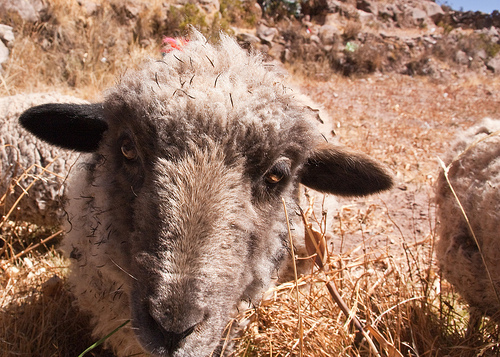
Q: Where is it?
A: This is at the field.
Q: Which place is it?
A: It is a field.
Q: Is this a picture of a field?
A: Yes, it is showing a field.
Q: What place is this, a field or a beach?
A: It is a field.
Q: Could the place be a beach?
A: No, it is a field.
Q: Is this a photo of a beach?
A: No, the picture is showing a field.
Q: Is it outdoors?
A: Yes, it is outdoors.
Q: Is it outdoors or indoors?
A: It is outdoors.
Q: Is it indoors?
A: No, it is outdoors.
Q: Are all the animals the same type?
A: Yes, all the animals are sheep.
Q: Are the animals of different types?
A: No, all the animals are sheep.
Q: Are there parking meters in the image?
A: No, there are no parking meters.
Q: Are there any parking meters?
A: No, there are no parking meters.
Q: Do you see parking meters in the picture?
A: No, there are no parking meters.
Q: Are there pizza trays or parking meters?
A: No, there are no parking meters or pizza trays.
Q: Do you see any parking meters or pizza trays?
A: No, there are no parking meters or pizza trays.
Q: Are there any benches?
A: No, there are no benches.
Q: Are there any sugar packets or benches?
A: No, there are no benches or sugar packets.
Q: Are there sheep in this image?
A: Yes, there is a sheep.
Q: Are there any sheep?
A: Yes, there is a sheep.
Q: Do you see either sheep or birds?
A: Yes, there is a sheep.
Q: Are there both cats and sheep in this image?
A: No, there is a sheep but no cats.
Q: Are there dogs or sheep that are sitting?
A: Yes, the sheep is sitting.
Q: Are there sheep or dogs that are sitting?
A: Yes, the sheep is sitting.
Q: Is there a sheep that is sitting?
A: Yes, there is a sheep that is sitting.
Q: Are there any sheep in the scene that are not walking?
A: Yes, there is a sheep that is sitting.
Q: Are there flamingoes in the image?
A: No, there are no flamingoes.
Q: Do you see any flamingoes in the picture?
A: No, there are no flamingoes.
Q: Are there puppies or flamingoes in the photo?
A: No, there are no flamingoes or puppies.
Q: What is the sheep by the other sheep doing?
A: The sheep is sitting.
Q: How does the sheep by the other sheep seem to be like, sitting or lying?
A: The sheep is sitting.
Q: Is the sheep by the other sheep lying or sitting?
A: The sheep is sitting.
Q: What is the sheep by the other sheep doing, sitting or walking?
A: The sheep is sitting.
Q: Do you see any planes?
A: No, there are no planes.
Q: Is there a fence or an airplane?
A: No, there are no airplanes or fences.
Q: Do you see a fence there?
A: No, there are no fences.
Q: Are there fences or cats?
A: No, there are no fences or cats.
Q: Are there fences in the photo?
A: No, there are no fences.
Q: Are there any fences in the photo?
A: No, there are no fences.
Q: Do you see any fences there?
A: No, there are no fences.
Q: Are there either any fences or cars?
A: No, there are no fences or cars.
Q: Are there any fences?
A: No, there are no fences.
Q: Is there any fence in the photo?
A: No, there are no fences.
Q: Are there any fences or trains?
A: No, there are no fences or trains.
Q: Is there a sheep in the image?
A: Yes, there is a sheep.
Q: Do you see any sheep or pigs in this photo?
A: Yes, there is a sheep.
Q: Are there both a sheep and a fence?
A: No, there is a sheep but no fences.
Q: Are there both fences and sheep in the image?
A: No, there is a sheep but no fences.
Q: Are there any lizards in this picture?
A: No, there are no lizards.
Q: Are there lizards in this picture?
A: No, there are no lizards.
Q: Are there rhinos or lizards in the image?
A: No, there are no lizards or rhinos.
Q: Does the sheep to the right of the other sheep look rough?
A: Yes, the sheep is rough.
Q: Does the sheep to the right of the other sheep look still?
A: No, the sheep is rough.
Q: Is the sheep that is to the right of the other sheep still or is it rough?
A: The sheep is rough.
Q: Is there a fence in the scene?
A: No, there are no fences.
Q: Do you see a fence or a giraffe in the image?
A: No, there are no fences or giraffes.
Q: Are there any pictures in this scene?
A: No, there are no pictures.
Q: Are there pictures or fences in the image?
A: No, there are no pictures or fences.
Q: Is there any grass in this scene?
A: Yes, there is grass.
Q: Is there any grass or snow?
A: Yes, there is grass.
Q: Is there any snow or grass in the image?
A: Yes, there is grass.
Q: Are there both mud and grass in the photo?
A: No, there is grass but no mud.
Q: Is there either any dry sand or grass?
A: Yes, there is dry grass.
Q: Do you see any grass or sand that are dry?
A: Yes, the grass is dry.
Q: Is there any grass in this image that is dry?
A: Yes, there is grass that is dry.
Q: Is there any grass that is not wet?
A: Yes, there is dry grass.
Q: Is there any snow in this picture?
A: No, there is no snow.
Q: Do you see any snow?
A: No, there is no snow.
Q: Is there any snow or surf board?
A: No, there are no snow or surfboards.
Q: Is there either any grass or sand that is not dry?
A: No, there is grass but it is dry.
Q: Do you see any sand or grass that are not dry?
A: No, there is grass but it is dry.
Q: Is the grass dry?
A: Yes, the grass is dry.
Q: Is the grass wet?
A: No, the grass is dry.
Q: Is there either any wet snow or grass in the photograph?
A: No, there is grass but it is dry.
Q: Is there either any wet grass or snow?
A: No, there is grass but it is dry.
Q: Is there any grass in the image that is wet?
A: No, there is grass but it is dry.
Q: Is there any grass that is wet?
A: No, there is grass but it is dry.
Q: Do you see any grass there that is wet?
A: No, there is grass but it is dry.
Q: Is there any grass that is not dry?
A: No, there is grass but it is dry.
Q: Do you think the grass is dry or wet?
A: The grass is dry.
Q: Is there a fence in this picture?
A: No, there are no fences.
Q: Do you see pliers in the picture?
A: No, there are no pliers.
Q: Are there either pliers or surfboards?
A: No, there are no pliers or surfboards.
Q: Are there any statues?
A: No, there are no statues.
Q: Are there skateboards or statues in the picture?
A: No, there are no statues or skateboards.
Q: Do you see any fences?
A: No, there are no fences.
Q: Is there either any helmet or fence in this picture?
A: No, there are no fences or helmets.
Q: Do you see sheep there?
A: Yes, there is a sheep.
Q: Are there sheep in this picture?
A: Yes, there is a sheep.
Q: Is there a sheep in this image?
A: Yes, there is a sheep.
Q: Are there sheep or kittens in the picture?
A: Yes, there is a sheep.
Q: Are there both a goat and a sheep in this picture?
A: No, there is a sheep but no goats.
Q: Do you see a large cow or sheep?
A: Yes, there is a large sheep.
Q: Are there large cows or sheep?
A: Yes, there is a large sheep.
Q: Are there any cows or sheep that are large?
A: Yes, the sheep is large.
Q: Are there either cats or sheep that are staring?
A: Yes, the sheep is staring.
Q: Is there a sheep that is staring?
A: Yes, there is a sheep that is staring.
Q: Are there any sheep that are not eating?
A: Yes, there is a sheep that is staring.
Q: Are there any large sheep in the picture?
A: Yes, there is a large sheep.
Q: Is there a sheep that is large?
A: Yes, there is a sheep that is large.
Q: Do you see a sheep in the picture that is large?
A: Yes, there is a sheep that is large.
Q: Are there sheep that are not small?
A: Yes, there is a large sheep.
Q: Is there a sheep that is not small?
A: Yes, there is a large sheep.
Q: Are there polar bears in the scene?
A: No, there are no polar bears.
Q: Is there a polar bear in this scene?
A: No, there are no polar bears.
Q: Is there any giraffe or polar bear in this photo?
A: No, there are no polar bears or giraffes.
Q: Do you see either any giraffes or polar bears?
A: No, there are no polar bears or giraffes.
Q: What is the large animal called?
A: The animal is a sheep.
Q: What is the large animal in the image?
A: The animal is a sheep.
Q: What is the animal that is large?
A: The animal is a sheep.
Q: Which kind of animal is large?
A: The animal is a sheep.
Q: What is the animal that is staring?
A: The animal is a sheep.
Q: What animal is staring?
A: The animal is a sheep.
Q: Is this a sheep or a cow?
A: This is a sheep.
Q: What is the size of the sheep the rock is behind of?
A: The sheep is large.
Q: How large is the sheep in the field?
A: The sheep is large.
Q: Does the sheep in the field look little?
A: No, the sheep is large.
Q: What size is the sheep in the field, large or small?
A: The sheep is large.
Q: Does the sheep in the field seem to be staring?
A: Yes, the sheep is staring.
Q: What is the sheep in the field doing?
A: The sheep is staring.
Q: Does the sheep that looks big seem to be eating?
A: No, the sheep is staring.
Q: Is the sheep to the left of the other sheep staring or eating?
A: The sheep is staring.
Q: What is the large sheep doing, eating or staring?
A: The sheep is staring.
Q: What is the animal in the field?
A: The animal is a sheep.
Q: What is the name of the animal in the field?
A: The animal is a sheep.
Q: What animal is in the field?
A: The animal is a sheep.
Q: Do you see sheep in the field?
A: Yes, there is a sheep in the field.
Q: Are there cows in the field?
A: No, there is a sheep in the field.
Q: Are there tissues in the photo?
A: No, there are no tissues.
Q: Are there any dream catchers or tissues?
A: No, there are no tissues or dream catchers.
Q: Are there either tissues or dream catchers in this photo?
A: No, there are no tissues or dream catchers.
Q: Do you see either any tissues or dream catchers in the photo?
A: No, there are no tissues or dream catchers.